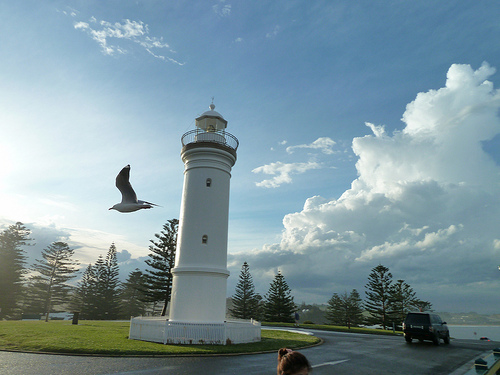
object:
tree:
[389, 280, 420, 323]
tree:
[260, 271, 299, 322]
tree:
[228, 261, 267, 320]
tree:
[133, 217, 179, 319]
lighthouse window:
[202, 234, 208, 244]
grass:
[0, 319, 320, 354]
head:
[274, 347, 312, 375]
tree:
[24, 239, 82, 321]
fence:
[129, 315, 261, 346]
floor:
[265, 218, 295, 273]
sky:
[0, 0, 500, 314]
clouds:
[285, 63, 499, 310]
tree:
[361, 262, 406, 330]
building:
[128, 96, 262, 345]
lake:
[358, 324, 499, 342]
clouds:
[56, 7, 186, 65]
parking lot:
[0, 325, 499, 374]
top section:
[181, 96, 240, 159]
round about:
[92, 303, 382, 374]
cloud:
[250, 161, 321, 187]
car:
[403, 311, 451, 345]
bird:
[108, 164, 164, 213]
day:
[15, 48, 499, 334]